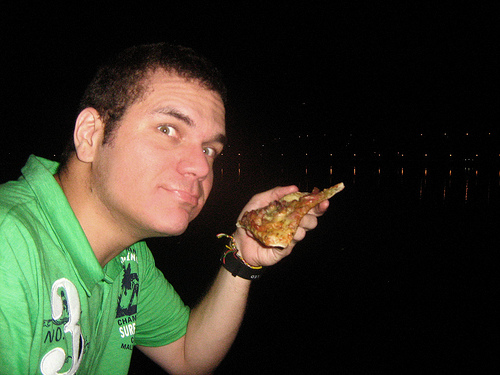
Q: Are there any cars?
A: No, there are no cars.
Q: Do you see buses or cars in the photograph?
A: No, there are no cars or buses.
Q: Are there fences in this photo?
A: No, there are no fences.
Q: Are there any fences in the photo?
A: No, there are no fences.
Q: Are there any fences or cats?
A: No, there are no fences or cats.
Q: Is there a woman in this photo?
A: No, there are no women.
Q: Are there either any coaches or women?
A: No, there are no women or coaches.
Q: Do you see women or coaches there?
A: No, there are no women or coaches.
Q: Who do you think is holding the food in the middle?
A: The man is holding the pizza.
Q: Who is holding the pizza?
A: The man is holding the pizza.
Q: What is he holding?
A: The man is holding the pizza.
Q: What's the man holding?
A: The man is holding the pizza.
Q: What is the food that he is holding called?
A: The food is a pizza.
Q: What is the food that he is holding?
A: The food is a pizza.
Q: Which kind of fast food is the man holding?
A: The man is holding the pizza.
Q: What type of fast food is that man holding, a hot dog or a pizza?
A: The man is holding a pizza.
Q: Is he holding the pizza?
A: Yes, the man is holding the pizza.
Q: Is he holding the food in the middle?
A: Yes, the man is holding the pizza.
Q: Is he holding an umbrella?
A: No, the man is holding the pizza.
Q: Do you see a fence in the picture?
A: No, there are no fences.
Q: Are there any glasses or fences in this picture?
A: No, there are no fences or glasses.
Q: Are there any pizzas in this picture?
A: Yes, there is a pizza.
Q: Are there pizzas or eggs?
A: Yes, there is a pizza.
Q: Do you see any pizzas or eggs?
A: Yes, there is a pizza.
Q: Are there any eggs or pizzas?
A: Yes, there is a pizza.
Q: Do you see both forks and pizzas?
A: No, there is a pizza but no forks.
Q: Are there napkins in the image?
A: No, there are no napkins.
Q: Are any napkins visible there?
A: No, there are no napkins.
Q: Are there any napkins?
A: No, there are no napkins.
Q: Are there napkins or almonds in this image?
A: No, there are no napkins or almonds.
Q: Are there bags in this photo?
A: No, there are no bags.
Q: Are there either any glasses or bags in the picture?
A: No, there are no bags or glasses.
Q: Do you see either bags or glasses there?
A: No, there are no bags or glasses.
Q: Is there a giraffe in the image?
A: No, there are no giraffes.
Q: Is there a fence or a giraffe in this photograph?
A: No, there are no giraffes or fences.